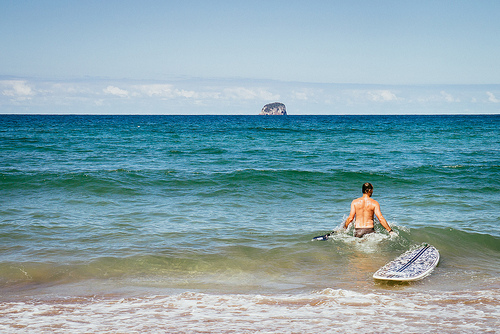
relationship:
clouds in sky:
[21, 60, 465, 113] [20, 8, 492, 107]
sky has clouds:
[20, 8, 492, 107] [21, 60, 465, 113]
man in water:
[328, 174, 394, 250] [186, 133, 407, 264]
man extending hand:
[328, 174, 394, 250] [375, 224, 407, 237]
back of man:
[346, 197, 379, 227] [328, 174, 394, 250]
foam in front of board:
[388, 219, 412, 254] [355, 242, 439, 303]